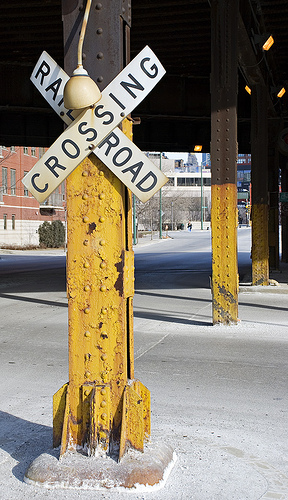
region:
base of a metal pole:
[12, 432, 190, 487]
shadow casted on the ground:
[0, 402, 56, 483]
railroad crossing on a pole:
[10, 39, 179, 201]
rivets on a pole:
[96, 343, 112, 445]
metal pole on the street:
[197, 159, 208, 237]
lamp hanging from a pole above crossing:
[58, 5, 108, 106]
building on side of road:
[3, 150, 60, 268]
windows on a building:
[2, 163, 18, 206]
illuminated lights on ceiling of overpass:
[244, 29, 285, 102]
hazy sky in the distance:
[166, 151, 188, 164]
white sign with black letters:
[24, 49, 177, 203]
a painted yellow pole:
[46, 105, 169, 466]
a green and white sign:
[195, 198, 210, 209]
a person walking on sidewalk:
[177, 213, 192, 239]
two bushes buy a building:
[28, 216, 73, 257]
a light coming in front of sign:
[58, 2, 130, 118]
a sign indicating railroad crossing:
[23, 47, 176, 202]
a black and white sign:
[12, 44, 183, 210]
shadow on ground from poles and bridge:
[4, 222, 278, 338]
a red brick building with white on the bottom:
[2, 149, 92, 256]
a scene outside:
[4, 23, 277, 498]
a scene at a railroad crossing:
[7, 26, 285, 498]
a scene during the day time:
[6, 21, 287, 499]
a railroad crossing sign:
[11, 39, 191, 230]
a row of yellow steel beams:
[20, 25, 286, 498]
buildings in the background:
[2, 136, 276, 264]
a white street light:
[59, 21, 109, 119]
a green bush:
[31, 204, 75, 264]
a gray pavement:
[0, 239, 283, 498]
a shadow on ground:
[0, 381, 73, 494]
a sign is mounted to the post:
[16, 46, 167, 206]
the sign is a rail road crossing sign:
[20, 36, 171, 209]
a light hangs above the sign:
[60, 3, 104, 111]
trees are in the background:
[133, 154, 206, 242]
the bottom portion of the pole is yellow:
[210, 183, 240, 324]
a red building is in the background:
[0, 149, 65, 223]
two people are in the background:
[186, 216, 195, 231]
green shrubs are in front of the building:
[36, 219, 67, 250]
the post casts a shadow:
[9, 291, 232, 332]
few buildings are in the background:
[131, 149, 249, 227]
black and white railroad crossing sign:
[22, 50, 171, 207]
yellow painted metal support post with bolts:
[59, 212, 144, 379]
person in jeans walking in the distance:
[183, 215, 195, 232]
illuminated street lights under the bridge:
[240, 22, 285, 101]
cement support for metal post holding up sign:
[13, 429, 206, 496]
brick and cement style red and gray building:
[6, 198, 32, 244]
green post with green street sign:
[193, 157, 208, 232]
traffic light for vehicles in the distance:
[244, 198, 251, 214]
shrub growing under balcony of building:
[34, 184, 66, 252]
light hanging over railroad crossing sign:
[62, 10, 108, 121]